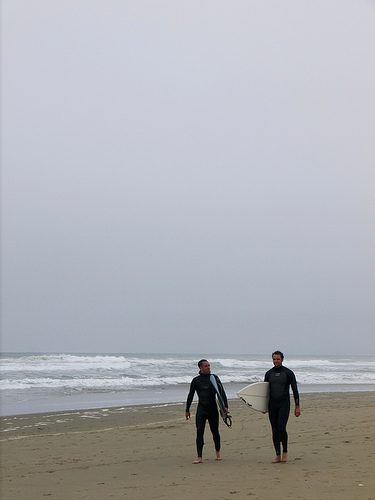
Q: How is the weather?
A: It is overcast.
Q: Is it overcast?
A: Yes, it is overcast.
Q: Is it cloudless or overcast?
A: It is overcast.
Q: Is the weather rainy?
A: No, it is overcast.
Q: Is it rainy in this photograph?
A: No, it is overcast.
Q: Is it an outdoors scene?
A: Yes, it is outdoors.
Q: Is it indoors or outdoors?
A: It is outdoors.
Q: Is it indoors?
A: No, it is outdoors.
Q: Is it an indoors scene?
A: No, it is outdoors.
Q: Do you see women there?
A: No, there are no women.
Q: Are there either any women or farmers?
A: No, there are no women or farmers.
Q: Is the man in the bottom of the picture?
A: Yes, the man is in the bottom of the image.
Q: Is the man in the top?
A: No, the man is in the bottom of the image.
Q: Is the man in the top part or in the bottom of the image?
A: The man is in the bottom of the image.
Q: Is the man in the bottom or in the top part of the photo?
A: The man is in the bottom of the image.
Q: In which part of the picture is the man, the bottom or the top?
A: The man is in the bottom of the image.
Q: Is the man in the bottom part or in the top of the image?
A: The man is in the bottom of the image.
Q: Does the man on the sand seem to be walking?
A: Yes, the man is walking.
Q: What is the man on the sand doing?
A: The man is walking.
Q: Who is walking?
A: The man is walking.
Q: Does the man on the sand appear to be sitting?
A: No, the man is walking.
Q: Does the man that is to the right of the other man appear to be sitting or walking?
A: The man is walking.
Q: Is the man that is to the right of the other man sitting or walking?
A: The man is walking.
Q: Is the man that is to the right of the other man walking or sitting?
A: The man is walking.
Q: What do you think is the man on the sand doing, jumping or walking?
A: The man is walking.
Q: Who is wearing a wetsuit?
A: The man is wearing a wetsuit.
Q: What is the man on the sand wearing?
A: The man is wearing a wetsuit.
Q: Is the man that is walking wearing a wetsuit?
A: Yes, the man is wearing a wetsuit.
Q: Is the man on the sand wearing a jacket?
A: No, the man is wearing a wetsuit.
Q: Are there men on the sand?
A: Yes, there is a man on the sand.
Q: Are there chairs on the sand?
A: No, there is a man on the sand.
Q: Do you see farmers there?
A: No, there are no farmers.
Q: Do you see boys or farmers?
A: No, there are no farmers or boys.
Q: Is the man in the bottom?
A: Yes, the man is in the bottom of the image.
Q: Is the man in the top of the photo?
A: No, the man is in the bottom of the image.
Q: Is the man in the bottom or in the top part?
A: The man is in the bottom of the image.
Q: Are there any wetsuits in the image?
A: Yes, there is a wetsuit.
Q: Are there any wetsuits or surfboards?
A: Yes, there is a wetsuit.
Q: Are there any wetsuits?
A: Yes, there is a wetsuit.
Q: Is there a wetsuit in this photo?
A: Yes, there is a wetsuit.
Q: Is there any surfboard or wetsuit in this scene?
A: Yes, there is a wetsuit.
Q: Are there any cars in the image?
A: No, there are no cars.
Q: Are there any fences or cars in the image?
A: No, there are no cars or fences.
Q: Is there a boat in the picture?
A: No, there are no boats.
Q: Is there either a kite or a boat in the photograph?
A: No, there are no boats or kites.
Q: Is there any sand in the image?
A: Yes, there is sand.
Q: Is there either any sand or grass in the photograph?
A: Yes, there is sand.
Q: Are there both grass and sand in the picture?
A: No, there is sand but no grass.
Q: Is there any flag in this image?
A: No, there are no flags.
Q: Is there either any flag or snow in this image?
A: No, there are no flags or snow.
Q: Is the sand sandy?
A: Yes, the sand is sandy.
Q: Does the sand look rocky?
A: No, the sand is sandy.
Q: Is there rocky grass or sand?
A: No, there is sand but it is sandy.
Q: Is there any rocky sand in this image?
A: No, there is sand but it is sandy.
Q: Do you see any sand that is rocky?
A: No, there is sand but it is sandy.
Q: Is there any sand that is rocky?
A: No, there is sand but it is sandy.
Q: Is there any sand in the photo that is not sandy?
A: No, there is sand but it is sandy.